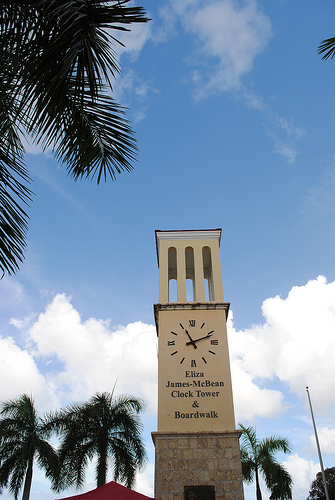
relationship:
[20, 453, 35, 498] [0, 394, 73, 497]
trunk of palm tree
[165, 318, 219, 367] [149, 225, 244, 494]
clock on tower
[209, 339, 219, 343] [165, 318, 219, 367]
roman numeral on clock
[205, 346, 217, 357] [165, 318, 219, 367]
roman numeral on clock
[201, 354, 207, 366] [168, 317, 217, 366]
roman numeral on clock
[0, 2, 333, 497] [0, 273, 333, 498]
sky between clouds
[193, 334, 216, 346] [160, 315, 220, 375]
hand attached to clock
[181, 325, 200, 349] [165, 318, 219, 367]
hand attached to clock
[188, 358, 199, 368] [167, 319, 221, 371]
roman numeral on a clock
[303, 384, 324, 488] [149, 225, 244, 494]
pole beside the tower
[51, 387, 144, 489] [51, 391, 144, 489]
leaves of the tree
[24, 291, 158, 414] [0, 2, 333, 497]
cloud hanging in sky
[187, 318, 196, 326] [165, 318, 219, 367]
roman numeral adorning clock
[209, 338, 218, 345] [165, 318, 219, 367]
roman numeral adorning clock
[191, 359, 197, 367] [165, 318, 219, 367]
roman numeral adorning clock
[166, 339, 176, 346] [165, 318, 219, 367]
roman numeral adorning clock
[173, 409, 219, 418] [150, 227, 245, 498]
word painted on building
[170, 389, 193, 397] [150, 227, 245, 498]
word painted on building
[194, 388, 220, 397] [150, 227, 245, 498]
word painted on building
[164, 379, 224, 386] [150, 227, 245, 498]
word painted on building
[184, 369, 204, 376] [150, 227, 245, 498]
word painted on building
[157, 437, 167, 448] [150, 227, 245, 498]
brick supporting building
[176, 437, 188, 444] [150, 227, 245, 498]
brick supporting building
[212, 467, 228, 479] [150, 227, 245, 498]
brick supporting building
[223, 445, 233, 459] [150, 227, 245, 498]
brick supporting building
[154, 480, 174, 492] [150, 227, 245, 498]
brick supporting building